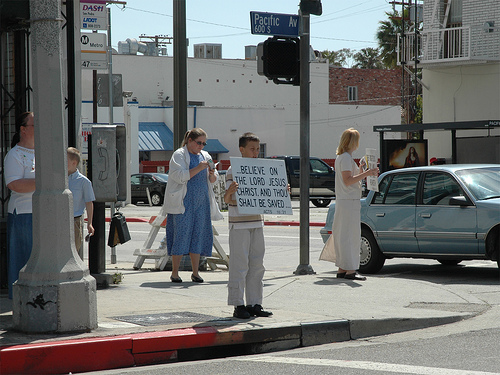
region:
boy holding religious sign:
[214, 124, 294, 322]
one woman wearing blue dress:
[156, 118, 221, 286]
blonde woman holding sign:
[326, 119, 383, 283]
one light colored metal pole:
[6, 0, 101, 338]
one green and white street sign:
[248, 5, 303, 37]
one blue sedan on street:
[325, 163, 499, 275]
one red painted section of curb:
[1, 319, 291, 374]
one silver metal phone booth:
[86, 119, 135, 291]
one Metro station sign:
[77, 30, 112, 75]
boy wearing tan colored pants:
[218, 125, 287, 323]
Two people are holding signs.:
[229, 132, 381, 297]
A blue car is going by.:
[321, 163, 498, 277]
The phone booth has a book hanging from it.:
[90, 121, 135, 246]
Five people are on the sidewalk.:
[5, 113, 375, 340]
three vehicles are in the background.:
[131, 153, 499, 271]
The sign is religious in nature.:
[228, 155, 295, 213]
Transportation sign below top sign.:
[81, 0, 121, 120]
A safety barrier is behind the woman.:
[135, 125, 225, 282]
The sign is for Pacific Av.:
[250, 7, 302, 37]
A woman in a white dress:
[327, 125, 387, 284]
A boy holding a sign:
[219, 130, 297, 320]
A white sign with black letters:
[225, 154, 299, 220]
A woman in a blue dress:
[156, 125, 223, 285]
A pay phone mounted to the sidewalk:
[82, 121, 133, 290]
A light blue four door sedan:
[315, 162, 498, 279]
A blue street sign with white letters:
[246, 8, 303, 39]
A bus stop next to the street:
[370, 114, 498, 205]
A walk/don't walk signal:
[254, 34, 305, 87]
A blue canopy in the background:
[81, 119, 188, 154]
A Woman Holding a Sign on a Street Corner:
[320, 118, 402, 309]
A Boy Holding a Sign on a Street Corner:
[214, 102, 309, 329]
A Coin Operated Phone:
[70, 100, 148, 275]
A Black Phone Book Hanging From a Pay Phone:
[108, 157, 143, 265]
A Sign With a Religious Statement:
[213, 143, 307, 244]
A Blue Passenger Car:
[327, 158, 499, 276]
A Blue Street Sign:
[241, 6, 344, 53]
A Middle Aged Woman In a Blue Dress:
[145, 120, 222, 295]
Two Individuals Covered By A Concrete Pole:
[7, 100, 104, 332]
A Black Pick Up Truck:
[265, 152, 341, 215]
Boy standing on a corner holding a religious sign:
[217, 130, 277, 317]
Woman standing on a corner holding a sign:
[330, 125, 385, 280]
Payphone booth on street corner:
[85, 120, 130, 290]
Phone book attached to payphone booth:
[100, 201, 135, 251]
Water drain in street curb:
[150, 330, 290, 362]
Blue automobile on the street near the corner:
[321, 162, 498, 275]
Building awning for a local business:
[136, 117, 232, 157]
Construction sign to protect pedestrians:
[138, 197, 233, 273]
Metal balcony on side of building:
[413, 13, 488, 70]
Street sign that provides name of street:
[241, 7, 305, 37]